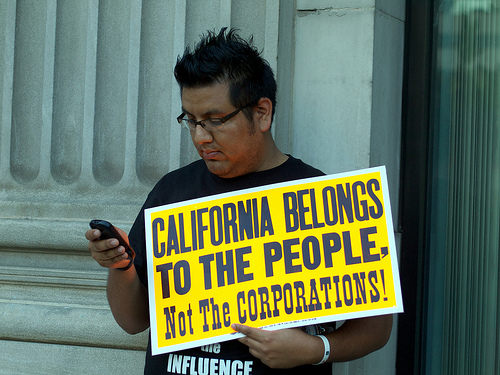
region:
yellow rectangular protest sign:
[138, 163, 410, 359]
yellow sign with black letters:
[144, 163, 407, 359]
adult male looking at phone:
[76, 22, 413, 373]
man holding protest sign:
[75, 22, 410, 374]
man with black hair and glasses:
[80, 22, 405, 373]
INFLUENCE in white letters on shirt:
[164, 349, 256, 374]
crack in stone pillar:
[290, 3, 407, 30]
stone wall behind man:
[4, 3, 411, 373]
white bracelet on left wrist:
[314, 330, 332, 368]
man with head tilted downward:
[80, 23, 407, 371]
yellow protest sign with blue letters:
[141, 165, 403, 357]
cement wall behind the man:
[2, 3, 395, 373]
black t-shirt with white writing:
[127, 155, 331, 374]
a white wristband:
[316, 335, 328, 363]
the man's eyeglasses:
[175, 108, 239, 123]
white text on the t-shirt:
[165, 339, 254, 373]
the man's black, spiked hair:
[174, 26, 277, 127]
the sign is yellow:
[269, 196, 284, 220]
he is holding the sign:
[219, 309, 276, 346]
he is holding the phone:
[84, 212, 138, 277]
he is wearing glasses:
[169, 115, 234, 132]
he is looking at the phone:
[72, 109, 239, 256]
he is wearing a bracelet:
[313, 334, 333, 371]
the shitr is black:
[172, 176, 207, 195]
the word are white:
[196, 356, 221, 373]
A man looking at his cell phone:
[84, 26, 284, 277]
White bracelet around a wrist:
[312, 329, 332, 370]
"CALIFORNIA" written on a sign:
[149, 193, 276, 259]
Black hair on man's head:
[170, 23, 283, 141]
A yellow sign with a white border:
[139, 163, 408, 359]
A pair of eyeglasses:
[173, 94, 263, 137]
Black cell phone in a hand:
[80, 214, 137, 278]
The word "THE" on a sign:
[195, 243, 257, 292]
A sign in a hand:
[139, 162, 408, 373]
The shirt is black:
[126, 154, 339, 373]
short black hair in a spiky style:
[170, 29, 288, 115]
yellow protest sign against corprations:
[145, 187, 395, 345]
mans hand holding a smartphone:
[85, 213, 135, 273]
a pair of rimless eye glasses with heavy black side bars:
[173, 109, 247, 132]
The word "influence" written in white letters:
[164, 355, 258, 373]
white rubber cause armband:
[317, 337, 333, 371]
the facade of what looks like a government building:
[0, 4, 497, 374]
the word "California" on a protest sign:
[147, 193, 272, 262]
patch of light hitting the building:
[418, 0, 498, 100]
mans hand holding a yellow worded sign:
[229, 316, 319, 373]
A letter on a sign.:
[154, 216, 166, 258]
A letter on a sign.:
[154, 262, 171, 299]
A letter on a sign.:
[174, 258, 189, 293]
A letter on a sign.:
[199, 252, 213, 288]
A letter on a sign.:
[213, 252, 232, 286]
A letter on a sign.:
[231, 244, 251, 282]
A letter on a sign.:
[263, 240, 278, 279]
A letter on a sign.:
[280, 239, 300, 273]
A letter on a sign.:
[303, 235, 319, 269]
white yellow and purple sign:
[142, 150, 407, 361]